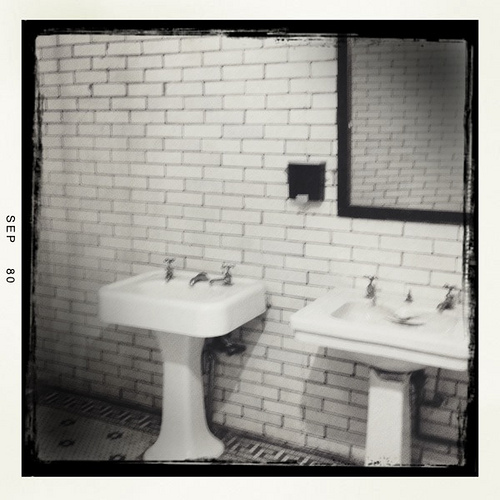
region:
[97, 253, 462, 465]
Pair of bathroom sinks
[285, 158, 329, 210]
Bathroom soap dispenser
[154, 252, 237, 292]
A silver sink faucet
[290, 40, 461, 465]
Bathroom sink and mirror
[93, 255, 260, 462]
A white porcelain standing sink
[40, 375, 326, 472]
Patterned bathroom floor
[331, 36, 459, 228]
A bathroom mirror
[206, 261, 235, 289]
Water knob on a sink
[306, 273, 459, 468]
Sink without a faucet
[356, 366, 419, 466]
A broken stand on a sink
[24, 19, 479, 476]
Interior, season and time, unclear.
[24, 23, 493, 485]
Old, black and white photo with unintact, black border.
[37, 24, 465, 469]
Public facility, showing two sinks and mirror.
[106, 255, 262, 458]
Curving, white pedestal with boxy sink and chrome fawcets.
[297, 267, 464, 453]
Straight, white pedestal with wide sink, showing lip, over edge.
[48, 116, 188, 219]
Brick wall, behind sinks.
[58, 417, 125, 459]
Floral pattern, on tile floor.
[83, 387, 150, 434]
Abstract border, on tile floor.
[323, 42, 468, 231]
Mirror, with eerie view of other brick wall.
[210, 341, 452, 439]
Pipes, behind sinks.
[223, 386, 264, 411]
The brick is white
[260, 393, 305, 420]
The brick is white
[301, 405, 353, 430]
The brick is white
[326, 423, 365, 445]
The brick is white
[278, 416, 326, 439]
The brick is white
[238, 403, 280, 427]
The brick is white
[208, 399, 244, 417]
The brick is white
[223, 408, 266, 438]
The brick is white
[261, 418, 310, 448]
The brick is white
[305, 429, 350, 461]
The brick is white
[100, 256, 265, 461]
A sink in the bathroom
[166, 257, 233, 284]
Faucets on the sink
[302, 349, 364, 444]
A shadow on the wall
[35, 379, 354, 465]
The floor beneath the sinks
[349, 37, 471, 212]
A mirror on the wall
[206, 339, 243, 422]
Pipes connected to the sink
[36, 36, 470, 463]
A wall behind the sink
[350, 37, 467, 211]
A wall in the mirror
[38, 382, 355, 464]
A floor beneath the mirror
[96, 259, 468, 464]
Sinks near the mirror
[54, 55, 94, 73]
The brick is white.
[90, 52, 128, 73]
The brick is white.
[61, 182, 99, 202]
The brick is white.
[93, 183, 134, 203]
The brick is white.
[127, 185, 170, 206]
The brick is white.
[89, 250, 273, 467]
The sink is white.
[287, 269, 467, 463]
The sink is white.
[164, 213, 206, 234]
The brick is white.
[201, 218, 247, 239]
The brick is white.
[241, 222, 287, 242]
The brick is white.